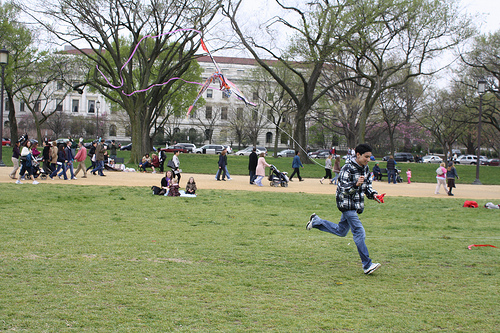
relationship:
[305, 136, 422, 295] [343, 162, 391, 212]
boy in flannel